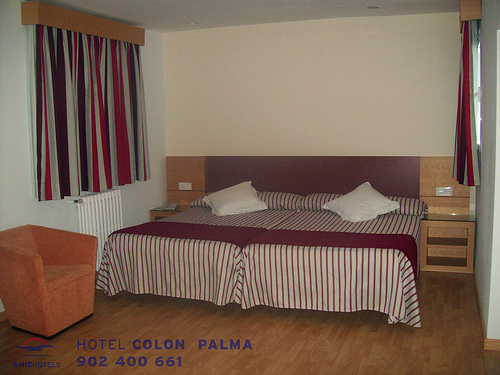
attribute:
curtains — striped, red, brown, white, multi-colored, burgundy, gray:
[28, 23, 487, 199]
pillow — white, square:
[202, 176, 270, 217]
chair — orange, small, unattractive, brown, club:
[2, 220, 105, 339]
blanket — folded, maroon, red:
[101, 217, 423, 283]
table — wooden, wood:
[418, 212, 485, 279]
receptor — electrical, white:
[177, 180, 193, 191]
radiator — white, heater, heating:
[74, 186, 127, 282]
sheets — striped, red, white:
[95, 183, 433, 328]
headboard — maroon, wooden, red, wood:
[162, 155, 478, 216]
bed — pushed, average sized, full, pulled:
[94, 183, 302, 309]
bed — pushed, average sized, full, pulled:
[231, 188, 430, 331]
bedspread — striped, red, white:
[97, 185, 429, 333]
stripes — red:
[96, 189, 428, 330]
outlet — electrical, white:
[433, 183, 458, 199]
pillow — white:
[320, 175, 401, 222]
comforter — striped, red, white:
[92, 188, 427, 336]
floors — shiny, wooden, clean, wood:
[5, 253, 500, 370]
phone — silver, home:
[150, 197, 179, 214]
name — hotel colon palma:
[76, 332, 254, 354]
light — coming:
[466, 16, 483, 202]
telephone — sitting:
[154, 201, 181, 215]